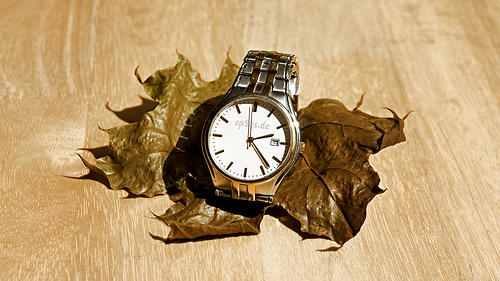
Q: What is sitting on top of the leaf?
A: A watch.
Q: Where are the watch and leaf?
A: The table.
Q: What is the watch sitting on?
A: A leaf.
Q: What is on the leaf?
A: A watch.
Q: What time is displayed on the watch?
A: 2:24.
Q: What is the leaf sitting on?
A: A wooden table.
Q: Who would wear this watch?
A: A man.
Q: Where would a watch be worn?
A: On a wrist.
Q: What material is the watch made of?
A: Silver metal.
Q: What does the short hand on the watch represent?
A: The hour.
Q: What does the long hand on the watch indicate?
A: The minute.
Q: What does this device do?
A: Tell time.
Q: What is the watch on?
A: A leaf.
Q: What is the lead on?
A: Wooden surface.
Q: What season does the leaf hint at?
A: Autumn.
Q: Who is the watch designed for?
A: A man.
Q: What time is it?
A: 2:23.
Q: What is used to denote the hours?
A: Larger lines.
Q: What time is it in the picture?
A: It is 2:23.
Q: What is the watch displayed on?
A: Leaves.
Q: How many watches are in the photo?
A: One.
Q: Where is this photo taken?
A: On a table.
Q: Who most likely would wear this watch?
A: Men.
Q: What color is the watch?
A: Looks like white gold, silver.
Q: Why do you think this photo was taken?
A: Advertising.